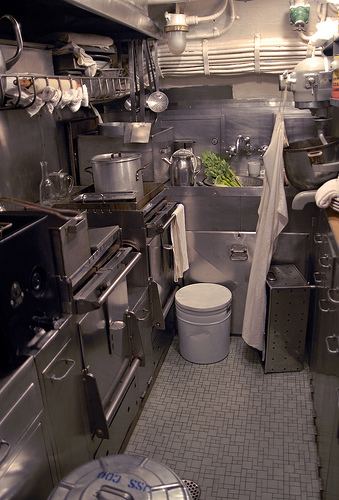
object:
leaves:
[205, 173, 209, 177]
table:
[86, 225, 122, 251]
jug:
[161, 147, 203, 186]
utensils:
[145, 31, 168, 116]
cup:
[247, 159, 261, 179]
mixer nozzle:
[277, 69, 291, 93]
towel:
[170, 201, 191, 284]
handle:
[156, 202, 186, 234]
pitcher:
[47, 168, 75, 201]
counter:
[36, 182, 191, 370]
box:
[262, 258, 313, 376]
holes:
[272, 346, 275, 350]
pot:
[84, 152, 151, 205]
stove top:
[75, 183, 173, 209]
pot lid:
[90, 150, 144, 165]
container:
[38, 160, 57, 207]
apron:
[238, 107, 292, 358]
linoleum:
[117, 334, 332, 500]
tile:
[203, 457, 211, 465]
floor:
[115, 323, 325, 499]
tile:
[184, 449, 193, 457]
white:
[267, 449, 278, 458]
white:
[245, 463, 251, 468]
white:
[289, 483, 300, 495]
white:
[288, 453, 299, 462]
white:
[250, 421, 262, 432]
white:
[244, 464, 255, 470]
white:
[236, 488, 247, 496]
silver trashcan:
[45, 453, 187, 499]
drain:
[181, 479, 198, 498]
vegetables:
[199, 149, 245, 189]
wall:
[181, 0, 339, 42]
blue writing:
[95, 469, 155, 496]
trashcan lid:
[41, 453, 189, 500]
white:
[195, 293, 217, 302]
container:
[172, 281, 234, 367]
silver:
[110, 165, 132, 179]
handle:
[49, 357, 76, 381]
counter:
[33, 316, 96, 476]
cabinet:
[0, 311, 110, 498]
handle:
[94, 249, 143, 306]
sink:
[188, 114, 260, 195]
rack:
[0, 53, 163, 118]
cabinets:
[135, 186, 186, 241]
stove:
[70, 179, 186, 257]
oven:
[41, 184, 192, 455]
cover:
[173, 281, 234, 312]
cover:
[287, 0, 312, 31]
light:
[307, 14, 339, 52]